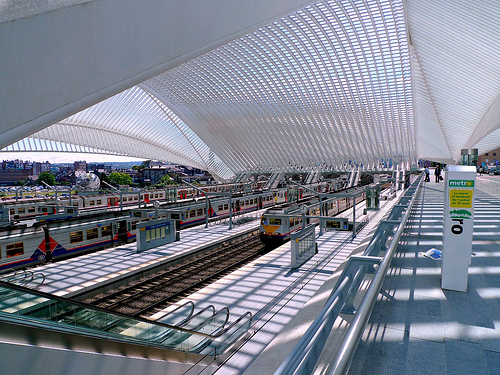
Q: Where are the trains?
A: On the tracks.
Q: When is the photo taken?
A: In the daytime.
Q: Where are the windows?
A: In the trains.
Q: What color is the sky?
A: Blue.